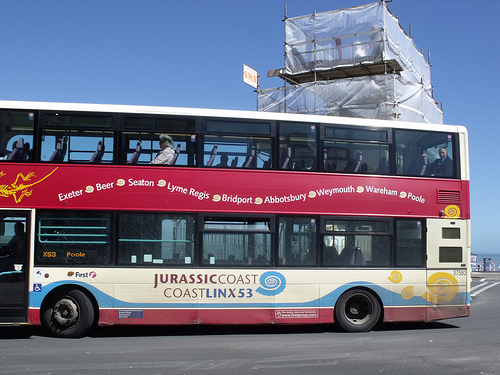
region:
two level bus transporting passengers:
[2, 89, 482, 334]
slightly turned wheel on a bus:
[31, 273, 105, 356]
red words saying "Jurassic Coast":
[150, 261, 263, 290]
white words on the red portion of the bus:
[38, 165, 443, 216]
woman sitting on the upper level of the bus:
[136, 131, 187, 173]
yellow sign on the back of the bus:
[390, 264, 480, 315]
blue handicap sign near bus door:
[31, 281, 46, 295]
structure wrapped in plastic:
[232, 11, 476, 134]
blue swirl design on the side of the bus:
[257, 266, 288, 301]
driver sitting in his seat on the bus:
[0, 216, 30, 281]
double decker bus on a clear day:
[2, 96, 479, 341]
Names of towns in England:
[53, 176, 431, 218]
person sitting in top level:
[148, 129, 177, 171]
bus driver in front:
[3, 211, 26, 283]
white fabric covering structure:
[307, 20, 375, 60]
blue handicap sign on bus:
[31, 277, 46, 300]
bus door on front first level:
[2, 200, 36, 324]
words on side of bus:
[148, 267, 290, 302]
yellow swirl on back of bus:
[416, 267, 459, 309]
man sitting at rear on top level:
[429, 141, 456, 175]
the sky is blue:
[61, 21, 199, 86]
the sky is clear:
[85, 20, 200, 85]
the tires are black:
[37, 284, 97, 341]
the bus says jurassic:
[145, 266, 217, 288]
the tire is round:
[38, 275, 100, 349]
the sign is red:
[75, 161, 384, 220]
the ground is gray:
[172, 340, 272, 372]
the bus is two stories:
[40, 90, 490, 353]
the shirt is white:
[155, 140, 177, 175]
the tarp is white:
[283, 11, 396, 88]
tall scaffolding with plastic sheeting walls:
[257, 0, 454, 120]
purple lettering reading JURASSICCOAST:
[145, 271, 285, 289]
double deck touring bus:
[0, 101, 471, 336]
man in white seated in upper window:
[147, 133, 183, 164]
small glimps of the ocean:
[469, 250, 499, 272]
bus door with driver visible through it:
[0, 209, 36, 330]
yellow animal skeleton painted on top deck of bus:
[0, 162, 64, 207]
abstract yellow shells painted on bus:
[389, 266, 468, 311]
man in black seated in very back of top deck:
[428, 145, 458, 179]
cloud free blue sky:
[1, 44, 498, 253]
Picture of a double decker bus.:
[3, 56, 488, 353]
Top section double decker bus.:
[0, 89, 476, 179]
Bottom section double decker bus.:
[2, 194, 489, 339]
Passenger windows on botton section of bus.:
[38, 191, 431, 276]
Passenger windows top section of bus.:
[11, 96, 471, 189]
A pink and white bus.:
[16, 94, 483, 341]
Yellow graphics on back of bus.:
[386, 202, 469, 309]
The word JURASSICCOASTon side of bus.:
[151, 267, 259, 284]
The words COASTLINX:
[163, 282, 235, 304]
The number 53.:
[237, 286, 254, 299]